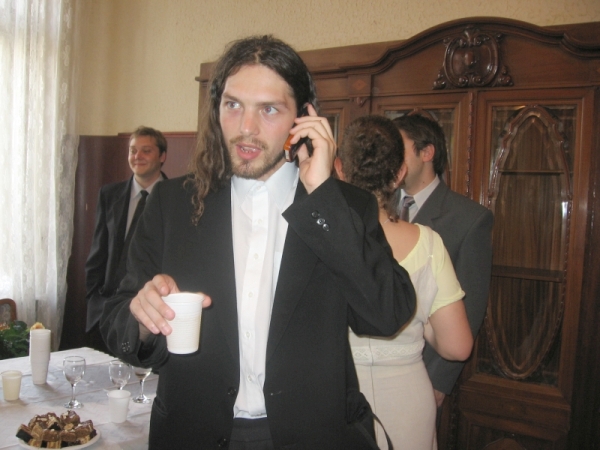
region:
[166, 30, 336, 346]
man talking on a cellphone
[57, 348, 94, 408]
wine glass on the table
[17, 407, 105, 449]
plate of sweets on the table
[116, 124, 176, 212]
guy wearing a tie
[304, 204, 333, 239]
buttons on the sleeve of the suit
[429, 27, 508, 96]
decorative design on the cabinet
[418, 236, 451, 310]
white dress on the woman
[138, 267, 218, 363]
hand holding a white cup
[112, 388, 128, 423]
white cup on the table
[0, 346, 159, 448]
A white table with food and glasses on it.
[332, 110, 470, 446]
The back of a woman in a light colored dress.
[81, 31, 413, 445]
Man with long hair talking on a phone.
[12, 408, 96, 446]
A plate of food on the table.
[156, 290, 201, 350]
White cup being held by long haired man.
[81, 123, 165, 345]
Smiling suited man standing by the wall.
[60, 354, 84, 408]
A wine glass on the table.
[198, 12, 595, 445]
A large piece of furniture with glass doors.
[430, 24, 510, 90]
Ornate decoration above glass doors of furniture.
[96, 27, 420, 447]
a man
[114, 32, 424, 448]
A man talking on a cellphone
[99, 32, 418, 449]
The man has long hair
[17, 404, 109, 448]
A desert plate on the table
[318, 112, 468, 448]
A woman in a white dress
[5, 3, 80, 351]
White lace curtains hang from the window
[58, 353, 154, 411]
Wine glasses on the table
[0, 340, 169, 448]
A white tablecloth on the table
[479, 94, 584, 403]
A glass in lay on the cabinet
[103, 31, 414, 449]
The man on the phone holds a white cup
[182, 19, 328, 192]
Man holding a cellphone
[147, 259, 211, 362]
man holding a white cup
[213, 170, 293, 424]
man wearing a white shirt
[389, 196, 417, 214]
man wearing a gray tie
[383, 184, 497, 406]
man wearing a gray jacket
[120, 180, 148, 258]
man wearing a black tie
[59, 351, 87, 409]
wine glasses on the table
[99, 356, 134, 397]
wine glasses on the table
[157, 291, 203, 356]
a vessel made for drinking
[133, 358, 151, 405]
a vessel made for drinking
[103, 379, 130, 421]
a vessel made for drinking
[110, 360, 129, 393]
a vessel made for drinking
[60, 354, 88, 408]
a vessel made for drinking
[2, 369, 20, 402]
a vessel made for drinking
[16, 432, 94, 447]
a plate made for dining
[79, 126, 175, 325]
a person is standing up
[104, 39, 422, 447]
a person is standing up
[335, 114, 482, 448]
a person is standing up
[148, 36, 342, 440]
man talking on phone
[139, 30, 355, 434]
man wearing white shirt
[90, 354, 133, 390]
glass on a table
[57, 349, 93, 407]
glass on a table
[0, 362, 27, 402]
cup on a table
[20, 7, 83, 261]
curtain on a window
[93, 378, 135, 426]
glass on a table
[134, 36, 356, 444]
man wearnig black jacket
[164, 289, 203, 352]
The cup in the man's hand.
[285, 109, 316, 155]
The phone in the man's hand.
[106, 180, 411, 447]
The black blazer the man on the phone is wearing.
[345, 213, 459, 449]
The yellow dress the woman is wearing.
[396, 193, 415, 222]
The tie the man in the gray suit is wearing.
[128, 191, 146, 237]
The tie the man in the black suit is wearing.